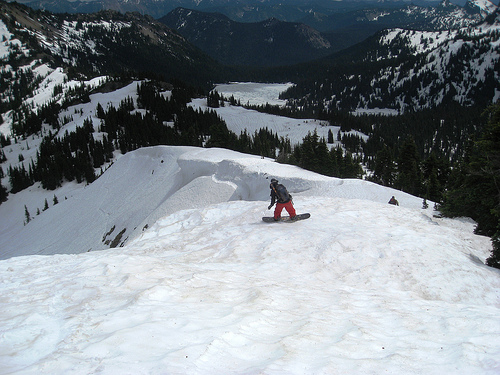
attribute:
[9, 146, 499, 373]
snow — white